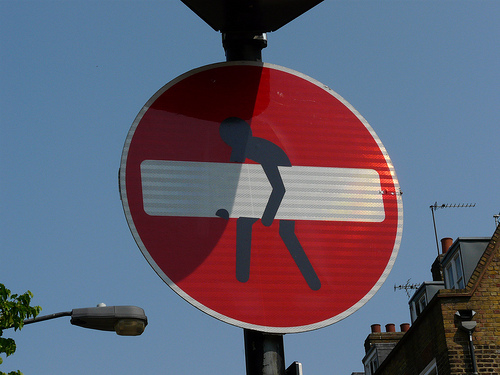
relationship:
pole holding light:
[0, 308, 71, 327] [69, 301, 148, 337]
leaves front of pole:
[1, 288, 41, 332] [0, 308, 71, 327]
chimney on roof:
[440, 237, 452, 254] [434, 234, 492, 263]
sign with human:
[118, 58, 406, 334] [216, 117, 322, 290]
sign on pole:
[118, 58, 406, 334] [181, 0, 307, 374]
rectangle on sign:
[139, 158, 386, 223] [118, 58, 406, 334]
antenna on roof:
[428, 202, 477, 259] [434, 234, 492, 263]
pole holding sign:
[181, 0, 307, 374] [118, 58, 406, 334]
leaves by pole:
[1, 288, 41, 332] [0, 308, 71, 327]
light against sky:
[1, 301, 148, 337] [1, 0, 498, 374]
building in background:
[371, 220, 499, 374] [1, 1, 497, 372]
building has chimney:
[371, 220, 499, 374] [440, 237, 452, 254]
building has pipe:
[371, 220, 499, 374] [453, 306, 482, 374]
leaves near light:
[1, 288, 41, 332] [1, 301, 148, 337]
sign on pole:
[118, 58, 406, 334] [0, 308, 71, 327]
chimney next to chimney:
[368, 322, 382, 335] [384, 322, 397, 335]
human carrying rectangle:
[216, 117, 322, 290] [139, 158, 386, 223]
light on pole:
[69, 301, 148, 337] [0, 308, 71, 327]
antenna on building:
[428, 202, 477, 259] [371, 220, 499, 374]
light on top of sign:
[182, 0, 324, 47] [118, 58, 406, 334]